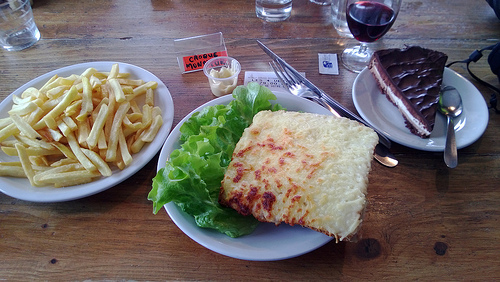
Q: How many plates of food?
A: Three.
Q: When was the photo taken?
A: Daytime.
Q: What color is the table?
A: Brown.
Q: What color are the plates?
A: White.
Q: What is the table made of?
A: Wood.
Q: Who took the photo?
A: A photographer.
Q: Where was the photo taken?
A: Near the food.